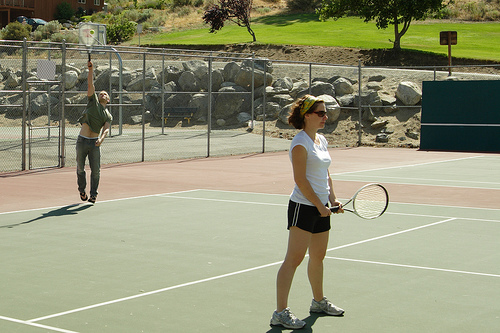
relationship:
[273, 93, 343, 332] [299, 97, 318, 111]
girl wearing headband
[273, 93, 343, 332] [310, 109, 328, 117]
girl wearing sunglasses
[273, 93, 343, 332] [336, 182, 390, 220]
girl holding racket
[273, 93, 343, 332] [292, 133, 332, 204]
girl wearing shirt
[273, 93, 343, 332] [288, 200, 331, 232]
girl wearing shorts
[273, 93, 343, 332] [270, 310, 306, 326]
girl wearing sneaker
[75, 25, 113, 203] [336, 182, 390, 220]
man swinging racket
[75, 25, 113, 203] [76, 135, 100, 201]
man wearing jeans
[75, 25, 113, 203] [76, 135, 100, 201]
adult wearing jeans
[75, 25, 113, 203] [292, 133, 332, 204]
adult wearing shirt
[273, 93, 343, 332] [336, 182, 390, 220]
woman holding racket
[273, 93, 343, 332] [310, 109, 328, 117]
woman wearing sunglasses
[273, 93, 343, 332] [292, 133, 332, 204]
woman wearing shirt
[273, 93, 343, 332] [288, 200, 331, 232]
woman wearing shorts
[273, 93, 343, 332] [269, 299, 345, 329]
woman wearing shoes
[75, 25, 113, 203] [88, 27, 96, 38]
man hitting ball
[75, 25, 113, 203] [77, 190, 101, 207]
man jumped in air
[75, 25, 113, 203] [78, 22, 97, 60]
man holding racket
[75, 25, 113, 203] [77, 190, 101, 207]
man jumping in air